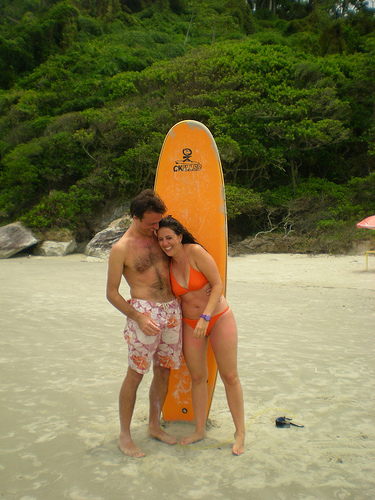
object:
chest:
[129, 242, 169, 274]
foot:
[232, 431, 245, 455]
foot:
[180, 430, 208, 446]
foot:
[147, 425, 178, 445]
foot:
[116, 437, 146, 458]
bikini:
[170, 244, 230, 337]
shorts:
[123, 298, 183, 375]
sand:
[0, 252, 375, 500]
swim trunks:
[123, 297, 183, 374]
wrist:
[201, 310, 212, 321]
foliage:
[285, 133, 295, 140]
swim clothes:
[170, 244, 230, 336]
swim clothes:
[123, 298, 183, 375]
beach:
[0, 250, 375, 500]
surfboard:
[153, 119, 229, 422]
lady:
[156, 214, 246, 456]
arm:
[192, 243, 223, 313]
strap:
[275, 413, 305, 427]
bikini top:
[170, 243, 210, 296]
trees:
[0, 0, 375, 219]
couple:
[105, 188, 245, 458]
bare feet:
[117, 437, 145, 458]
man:
[105, 188, 213, 458]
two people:
[105, 188, 245, 458]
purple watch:
[200, 314, 211, 322]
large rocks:
[0, 213, 134, 260]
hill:
[0, 0, 375, 251]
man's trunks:
[153, 223, 160, 230]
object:
[276, 416, 305, 428]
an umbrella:
[356, 215, 375, 230]